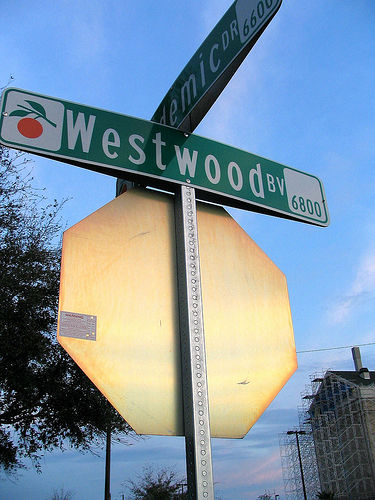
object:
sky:
[0, 1, 373, 500]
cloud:
[321, 248, 374, 332]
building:
[306, 344, 374, 500]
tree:
[0, 73, 151, 490]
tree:
[119, 462, 190, 500]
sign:
[55, 185, 299, 443]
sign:
[0, 85, 329, 229]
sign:
[114, 0, 283, 199]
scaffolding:
[276, 368, 375, 500]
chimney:
[350, 345, 363, 371]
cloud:
[241, 449, 283, 489]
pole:
[174, 184, 216, 500]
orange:
[15, 117, 45, 140]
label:
[59, 310, 98, 342]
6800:
[291, 194, 323, 218]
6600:
[242, 0, 275, 38]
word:
[65, 108, 266, 200]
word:
[266, 173, 285, 196]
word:
[157, 42, 223, 129]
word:
[220, 19, 241, 53]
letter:
[66, 109, 98, 154]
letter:
[173, 143, 200, 178]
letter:
[101, 127, 121, 160]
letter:
[167, 99, 179, 127]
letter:
[127, 133, 146, 166]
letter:
[151, 132, 167, 171]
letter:
[203, 154, 223, 186]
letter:
[227, 160, 245, 192]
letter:
[248, 162, 265, 199]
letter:
[221, 30, 231, 51]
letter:
[179, 73, 197, 113]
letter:
[198, 51, 207, 88]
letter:
[208, 42, 221, 73]